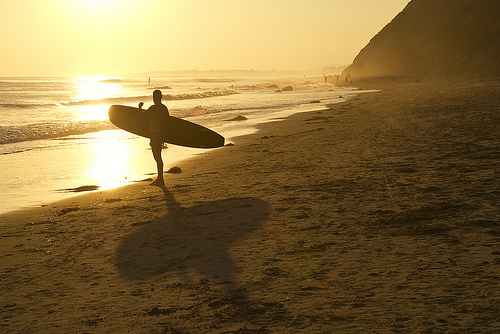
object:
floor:
[347, 154, 392, 191]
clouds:
[4, 0, 80, 24]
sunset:
[63, 0, 149, 191]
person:
[345, 76, 348, 85]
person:
[325, 76, 327, 83]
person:
[335, 75, 339, 81]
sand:
[173, 259, 275, 293]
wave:
[206, 120, 232, 128]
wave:
[0, 91, 238, 106]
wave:
[147, 86, 173, 90]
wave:
[97, 78, 143, 82]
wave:
[0, 79, 73, 83]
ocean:
[0, 79, 382, 214]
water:
[25, 150, 141, 171]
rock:
[222, 115, 248, 121]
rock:
[163, 166, 181, 173]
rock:
[281, 86, 293, 92]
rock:
[266, 84, 278, 88]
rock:
[275, 89, 281, 92]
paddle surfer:
[148, 77, 150, 85]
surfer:
[138, 90, 169, 186]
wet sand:
[0, 219, 59, 255]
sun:
[82, 0, 131, 24]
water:
[0, 156, 57, 211]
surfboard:
[107, 105, 224, 149]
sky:
[0, 0, 402, 73]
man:
[138, 89, 169, 185]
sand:
[309, 223, 500, 334]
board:
[108, 105, 225, 149]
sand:
[181, 166, 318, 210]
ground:
[0, 75, 500, 333]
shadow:
[113, 187, 269, 307]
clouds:
[23, 8, 46, 26]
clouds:
[43, 21, 92, 46]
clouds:
[158, 8, 199, 22]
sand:
[307, 120, 498, 200]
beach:
[0, 74, 283, 144]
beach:
[0, 71, 500, 331]